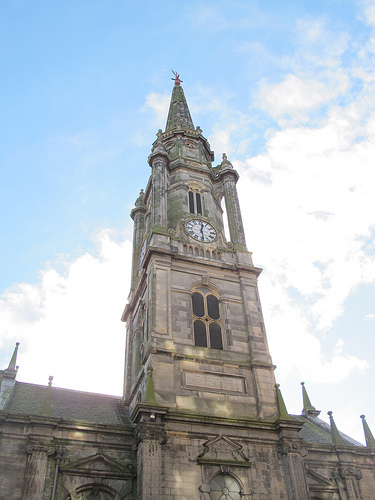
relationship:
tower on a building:
[116, 66, 283, 418] [0, 337, 360, 484]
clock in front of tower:
[185, 218, 217, 242] [116, 66, 283, 418]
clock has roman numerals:
[183, 215, 217, 244] [186, 218, 214, 241]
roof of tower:
[157, 83, 196, 132] [116, 66, 283, 418]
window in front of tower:
[191, 283, 225, 349] [116, 66, 283, 418]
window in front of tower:
[189, 189, 202, 216] [116, 66, 283, 418]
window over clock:
[183, 181, 206, 211] [178, 214, 218, 244]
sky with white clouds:
[3, 21, 361, 402] [238, 59, 362, 374]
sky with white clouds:
[3, 21, 361, 402] [10, 231, 123, 381]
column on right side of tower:
[214, 155, 251, 257] [116, 66, 283, 418]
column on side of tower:
[146, 128, 171, 232] [116, 66, 283, 418]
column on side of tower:
[128, 185, 145, 280] [116, 66, 283, 418]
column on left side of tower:
[146, 128, 171, 232] [116, 66, 283, 418]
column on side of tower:
[215, 153, 249, 251] [116, 66, 283, 418]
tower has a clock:
[116, 66, 283, 418] [183, 217, 220, 243]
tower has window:
[116, 66, 283, 418] [191, 283, 225, 349]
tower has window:
[116, 66, 283, 418] [189, 189, 202, 216]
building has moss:
[1, 64, 363, 495] [142, 370, 161, 404]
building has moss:
[1, 64, 363, 495] [249, 387, 289, 421]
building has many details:
[1, 64, 363, 495] [275, 429, 307, 457]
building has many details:
[1, 64, 363, 495] [163, 132, 199, 159]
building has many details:
[1, 64, 363, 495] [170, 242, 224, 263]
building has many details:
[1, 64, 363, 495] [137, 420, 167, 443]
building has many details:
[1, 64, 363, 495] [198, 434, 247, 459]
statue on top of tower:
[170, 69, 186, 86] [107, 76, 290, 418]